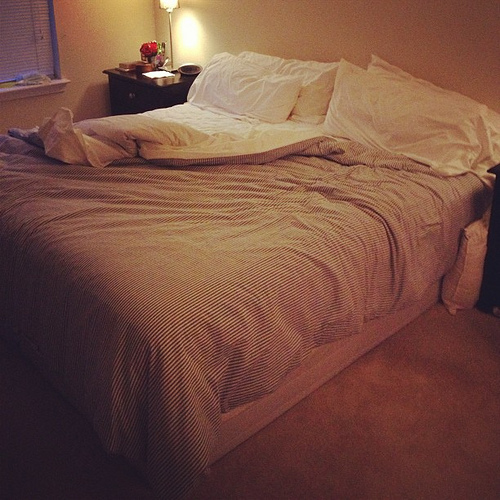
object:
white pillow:
[320, 57, 495, 185]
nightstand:
[102, 56, 197, 116]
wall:
[14, 321, 160, 472]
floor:
[0, 294, 500, 498]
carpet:
[384, 350, 490, 490]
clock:
[174, 56, 209, 78]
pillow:
[312, 57, 497, 182]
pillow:
[438, 201, 491, 313]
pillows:
[181, 29, 496, 183]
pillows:
[327, 58, 490, 175]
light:
[151, 0, 202, 62]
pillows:
[210, 33, 381, 167]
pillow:
[185, 53, 305, 125]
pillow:
[364, 52, 498, 165]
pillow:
[235, 47, 335, 123]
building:
[1, 1, 498, 498]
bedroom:
[10, 20, 486, 498]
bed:
[4, 46, 495, 478]